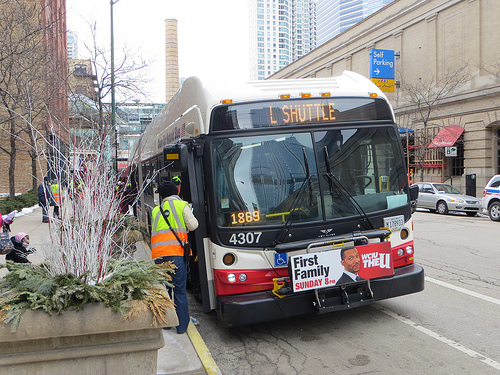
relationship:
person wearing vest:
[146, 171, 204, 328] [144, 199, 199, 263]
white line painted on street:
[421, 269, 498, 311] [185, 209, 497, 371]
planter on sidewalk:
[11, 259, 138, 351] [21, 205, 113, 259]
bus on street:
[118, 70, 425, 332] [178, 180, 497, 371]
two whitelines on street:
[370, 272, 499, 374] [428, 209, 498, 371]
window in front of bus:
[213, 122, 413, 232] [118, 70, 425, 332]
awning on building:
[425, 123, 467, 150] [263, 0, 498, 214]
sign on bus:
[269, 249, 294, 269] [118, 70, 425, 332]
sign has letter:
[370, 47, 396, 77] [371, 49, 376, 56]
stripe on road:
[373, 302, 498, 369] [424, 215, 497, 372]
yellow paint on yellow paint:
[186, 318, 223, 373] [186, 318, 223, 373]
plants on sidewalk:
[9, 89, 183, 373] [13, 184, 223, 373]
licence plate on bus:
[379, 215, 409, 235] [118, 70, 425, 332]